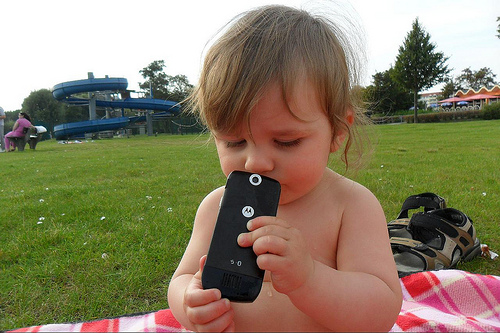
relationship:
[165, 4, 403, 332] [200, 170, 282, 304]
baby holding phone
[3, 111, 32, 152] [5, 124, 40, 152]
person sitting on bench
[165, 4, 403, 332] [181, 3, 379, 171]
baby has hair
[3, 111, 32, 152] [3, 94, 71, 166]
person on bench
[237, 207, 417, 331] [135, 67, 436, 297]
hand of child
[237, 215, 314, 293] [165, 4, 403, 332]
hand of baby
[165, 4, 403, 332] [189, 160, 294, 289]
baby holding smartphone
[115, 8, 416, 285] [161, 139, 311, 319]
baby has phone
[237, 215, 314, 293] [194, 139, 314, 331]
hand of phone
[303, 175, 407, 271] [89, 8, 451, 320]
arm of baby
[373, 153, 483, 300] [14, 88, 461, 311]
shoes on ground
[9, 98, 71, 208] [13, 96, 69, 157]
person on bench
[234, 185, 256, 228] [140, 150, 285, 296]
emblem on phone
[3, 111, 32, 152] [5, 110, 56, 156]
person on bench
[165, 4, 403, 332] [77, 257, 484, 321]
baby on blanket